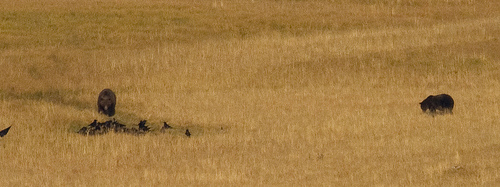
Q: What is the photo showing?
A: It is showing a field.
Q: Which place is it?
A: It is a field.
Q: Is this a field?
A: Yes, it is a field.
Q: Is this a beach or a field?
A: It is a field.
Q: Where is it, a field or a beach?
A: It is a field.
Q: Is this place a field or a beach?
A: It is a field.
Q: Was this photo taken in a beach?
A: No, the picture was taken in a field.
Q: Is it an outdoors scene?
A: Yes, it is outdoors.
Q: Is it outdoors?
A: Yes, it is outdoors.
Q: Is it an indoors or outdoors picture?
A: It is outdoors.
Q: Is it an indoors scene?
A: No, it is outdoors.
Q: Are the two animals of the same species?
A: Yes, all the animals are bears.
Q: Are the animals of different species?
A: No, all the animals are bears.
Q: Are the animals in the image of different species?
A: No, all the animals are bears.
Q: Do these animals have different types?
A: No, all the animals are bears.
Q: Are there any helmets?
A: No, there are no helmets.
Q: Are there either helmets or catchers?
A: No, there are no helmets or catchers.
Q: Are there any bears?
A: Yes, there is a bear.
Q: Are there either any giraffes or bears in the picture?
A: Yes, there is a bear.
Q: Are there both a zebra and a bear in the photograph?
A: No, there is a bear but no zebras.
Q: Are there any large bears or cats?
A: Yes, there is a large bear.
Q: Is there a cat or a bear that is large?
A: Yes, the bear is large.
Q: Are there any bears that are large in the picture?
A: Yes, there is a large bear.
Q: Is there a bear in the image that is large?
A: Yes, there is a bear that is large.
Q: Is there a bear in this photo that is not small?
A: Yes, there is a large bear.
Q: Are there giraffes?
A: No, there are no giraffes.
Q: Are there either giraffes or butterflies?
A: No, there are no giraffes or butterflies.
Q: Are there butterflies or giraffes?
A: No, there are no giraffes or butterflies.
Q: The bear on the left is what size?
A: The bear is large.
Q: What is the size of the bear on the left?
A: The bear is large.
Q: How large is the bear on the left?
A: The bear is large.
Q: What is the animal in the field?
A: The animal is a bear.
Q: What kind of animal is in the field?
A: The animal is a bear.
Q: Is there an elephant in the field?
A: No, there is a bear in the field.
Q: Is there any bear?
A: Yes, there is a bear.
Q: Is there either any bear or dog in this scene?
A: Yes, there is a bear.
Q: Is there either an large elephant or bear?
A: Yes, there is a large bear.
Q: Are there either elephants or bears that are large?
A: Yes, the bear is large.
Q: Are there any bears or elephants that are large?
A: Yes, the bear is large.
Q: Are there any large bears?
A: Yes, there is a large bear.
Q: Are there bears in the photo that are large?
A: Yes, there is a bear that is large.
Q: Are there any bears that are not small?
A: Yes, there is a large bear.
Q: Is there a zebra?
A: No, there are no zebras.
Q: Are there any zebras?
A: No, there are no zebras.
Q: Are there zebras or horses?
A: No, there are no zebras or horses.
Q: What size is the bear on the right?
A: The bear is large.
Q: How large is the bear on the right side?
A: The bear is large.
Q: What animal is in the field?
A: The animal is a bear.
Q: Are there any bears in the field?
A: Yes, there is a bear in the field.